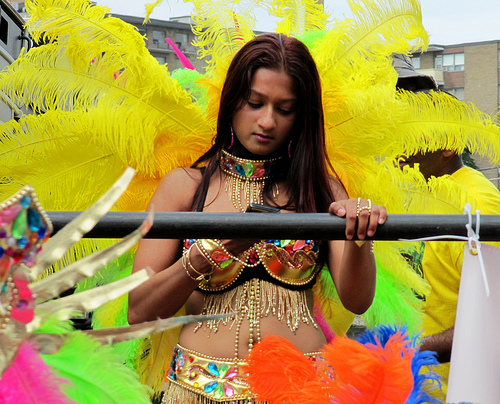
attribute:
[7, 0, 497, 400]
outfit — feathery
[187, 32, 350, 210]
hair — long, dark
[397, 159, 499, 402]
shirt — yellow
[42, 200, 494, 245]
pole — black, metal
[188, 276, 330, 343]
beads — gold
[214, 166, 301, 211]
beads — gold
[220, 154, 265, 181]
gems — colorful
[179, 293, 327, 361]
stomach — showing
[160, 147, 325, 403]
costume — elaborate